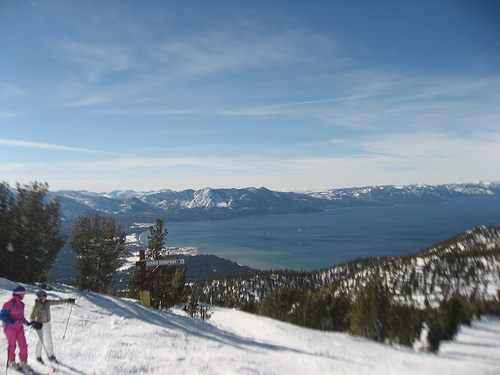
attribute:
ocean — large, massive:
[205, 207, 453, 277]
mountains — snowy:
[74, 183, 491, 210]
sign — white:
[136, 254, 198, 273]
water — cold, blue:
[225, 215, 391, 259]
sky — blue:
[17, 6, 499, 155]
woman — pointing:
[33, 288, 82, 360]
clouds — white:
[68, 84, 265, 163]